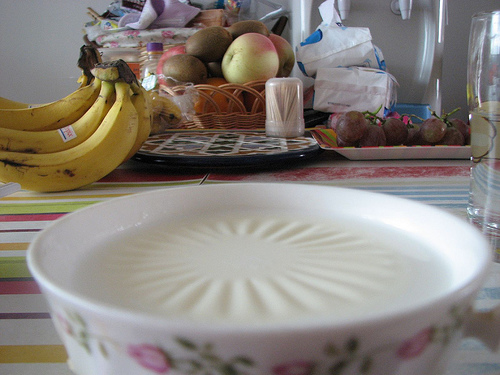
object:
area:
[0, 0, 499, 375]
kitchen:
[0, 0, 499, 375]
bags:
[295, 0, 398, 126]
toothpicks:
[267, 83, 301, 124]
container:
[265, 77, 305, 138]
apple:
[222, 31, 280, 84]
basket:
[153, 79, 269, 130]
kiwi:
[161, 54, 209, 86]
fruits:
[154, 20, 295, 81]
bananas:
[0, 59, 153, 193]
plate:
[310, 121, 472, 161]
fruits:
[327, 103, 472, 147]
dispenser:
[23, 177, 491, 374]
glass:
[466, 7, 499, 264]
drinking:
[465, 9, 499, 236]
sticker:
[58, 125, 77, 143]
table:
[0, 151, 500, 374]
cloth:
[0, 166, 499, 374]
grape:
[332, 109, 375, 142]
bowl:
[22, 181, 497, 373]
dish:
[23, 181, 490, 374]